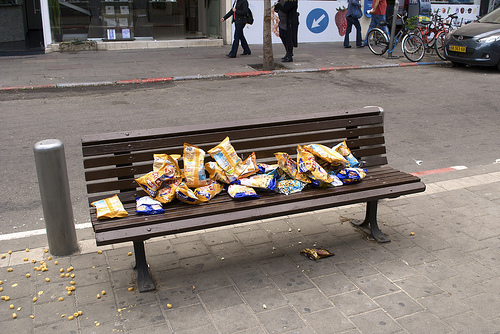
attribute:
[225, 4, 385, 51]
people — few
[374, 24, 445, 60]
bicycles — some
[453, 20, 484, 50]
car — blue, parked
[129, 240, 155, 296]
leg — bottom, metal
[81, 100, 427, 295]
bench — wooden, metal, outdoor, brown, black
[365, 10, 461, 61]
bicycles — several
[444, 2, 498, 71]
sedan — dark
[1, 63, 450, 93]
curb — red, white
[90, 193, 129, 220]
bag — yellow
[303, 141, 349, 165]
bag — yellow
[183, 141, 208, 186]
bag — yellow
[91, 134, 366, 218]
bags — several, yellow, chips, unopened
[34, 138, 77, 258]
post — gray, concrete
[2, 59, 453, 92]
curb — red, gray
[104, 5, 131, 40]
labels — white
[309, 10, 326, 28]
arrow — white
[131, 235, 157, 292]
bottom — black, metallic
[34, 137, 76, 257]
pole — short, wide, metal, small, silver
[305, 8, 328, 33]
sign — blue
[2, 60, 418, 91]
curb — white, red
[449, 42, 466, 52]
license plate — yellow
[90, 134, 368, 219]
packets — chips, cheese balls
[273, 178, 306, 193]
packet — chips, cheese balls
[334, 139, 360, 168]
packet — chips, cheese balls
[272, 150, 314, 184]
packet — chips, cheese balls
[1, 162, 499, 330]
sidewalk — blocked, concrete, tiled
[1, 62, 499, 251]
road — small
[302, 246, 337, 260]
pack — snack